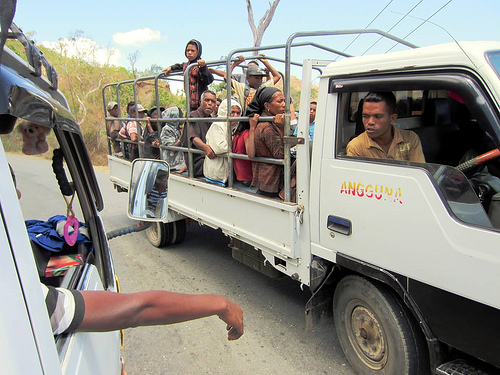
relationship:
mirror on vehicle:
[71, 151, 197, 269] [2, 3, 170, 368]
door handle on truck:
[326, 214, 353, 235] [98, 19, 497, 373]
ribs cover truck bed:
[92, 52, 334, 229] [104, 130, 311, 290]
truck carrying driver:
[98, 89, 469, 307] [345, 90, 425, 163]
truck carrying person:
[98, 89, 469, 307] [245, 85, 296, 201]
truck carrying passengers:
[98, 89, 469, 307] [174, 38, 207, 107]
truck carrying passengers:
[98, 89, 469, 307] [104, 93, 124, 141]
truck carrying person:
[98, 89, 469, 307] [202, 98, 241, 184]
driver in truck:
[346, 91, 426, 163] [98, 19, 497, 373]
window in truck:
[337, 75, 498, 229] [98, 19, 497, 373]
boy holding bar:
[161, 39, 215, 112] [224, 64, 236, 191]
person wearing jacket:
[201, 97, 241, 187] [166, 35, 213, 110]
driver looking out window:
[345, 90, 425, 163] [339, 66, 494, 199]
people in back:
[104, 37, 319, 209] [98, 25, 420, 298]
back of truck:
[98, 25, 420, 298] [98, 19, 497, 373]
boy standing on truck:
[171, 37, 211, 107] [98, 19, 497, 373]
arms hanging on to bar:
[224, 55, 279, 85] [184, 55, 301, 177]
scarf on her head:
[235, 84, 277, 140] [260, 85, 288, 117]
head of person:
[260, 85, 288, 117] [245, 85, 296, 201]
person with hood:
[202, 98, 241, 184] [218, 97, 241, 123]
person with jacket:
[202, 98, 241, 184] [200, 96, 242, 185]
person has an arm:
[7, 160, 247, 341] [52, 285, 245, 342]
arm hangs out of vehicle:
[52, 285, 245, 342] [1, 2, 124, 374]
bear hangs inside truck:
[0, 101, 67, 174] [4, 87, 182, 334]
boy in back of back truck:
[294, 95, 321, 142] [85, 40, 347, 250]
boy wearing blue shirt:
[294, 95, 321, 142] [296, 123, 326, 139]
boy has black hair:
[294, 95, 321, 142] [294, 97, 326, 113]